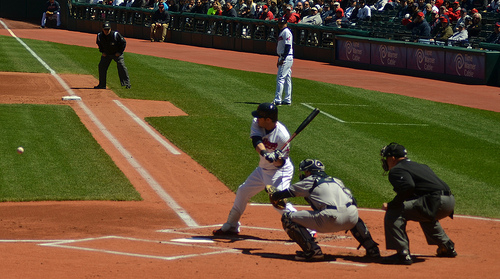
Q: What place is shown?
A: It is a field.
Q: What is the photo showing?
A: It is showing a field.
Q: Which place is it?
A: It is a field.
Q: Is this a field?
A: Yes, it is a field.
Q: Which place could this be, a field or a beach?
A: It is a field.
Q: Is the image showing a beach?
A: No, the picture is showing a field.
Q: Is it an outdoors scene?
A: Yes, it is outdoors.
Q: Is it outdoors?
A: Yes, it is outdoors.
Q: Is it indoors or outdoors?
A: It is outdoors.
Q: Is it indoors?
A: No, it is outdoors.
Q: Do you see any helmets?
A: Yes, there is a helmet.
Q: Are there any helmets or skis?
A: Yes, there is a helmet.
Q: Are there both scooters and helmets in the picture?
A: No, there is a helmet but no scooters.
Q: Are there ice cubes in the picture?
A: No, there are no ice cubes.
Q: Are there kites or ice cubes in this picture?
A: No, there are no ice cubes or kites.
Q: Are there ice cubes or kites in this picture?
A: No, there are no ice cubes or kites.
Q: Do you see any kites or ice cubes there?
A: No, there are no ice cubes or kites.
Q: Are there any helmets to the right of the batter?
A: Yes, there is a helmet to the right of the batter.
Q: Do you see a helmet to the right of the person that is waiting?
A: Yes, there is a helmet to the right of the batter.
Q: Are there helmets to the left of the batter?
A: No, the helmet is to the right of the batter.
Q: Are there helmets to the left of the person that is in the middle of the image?
A: No, the helmet is to the right of the batter.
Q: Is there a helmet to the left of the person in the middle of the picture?
A: No, the helmet is to the right of the batter.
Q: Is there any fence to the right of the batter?
A: No, there is a helmet to the right of the batter.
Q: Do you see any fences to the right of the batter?
A: No, there is a helmet to the right of the batter.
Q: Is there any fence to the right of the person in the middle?
A: No, there is a helmet to the right of the batter.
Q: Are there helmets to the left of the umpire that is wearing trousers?
A: Yes, there is a helmet to the left of the umpire.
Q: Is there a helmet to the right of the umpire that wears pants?
A: No, the helmet is to the left of the umpire.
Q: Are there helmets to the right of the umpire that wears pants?
A: No, the helmet is to the left of the umpire.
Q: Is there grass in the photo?
A: Yes, there is grass.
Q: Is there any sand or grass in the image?
A: Yes, there is grass.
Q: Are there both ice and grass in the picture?
A: No, there is grass but no ice.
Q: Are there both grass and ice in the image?
A: No, there is grass but no ice.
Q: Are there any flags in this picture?
A: No, there are no flags.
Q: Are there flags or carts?
A: No, there are no flags or carts.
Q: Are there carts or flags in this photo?
A: No, there are no flags or carts.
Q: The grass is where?
A: The grass is on the field.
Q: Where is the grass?
A: The grass is on the field.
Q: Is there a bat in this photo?
A: Yes, there is a bat.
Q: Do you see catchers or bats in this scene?
A: Yes, there is a bat.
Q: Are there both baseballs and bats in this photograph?
A: Yes, there are both a bat and a baseball.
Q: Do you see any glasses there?
A: No, there are no glasses.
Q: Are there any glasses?
A: No, there are no glasses.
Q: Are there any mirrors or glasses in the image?
A: No, there are no glasses or mirrors.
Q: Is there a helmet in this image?
A: Yes, there is a helmet.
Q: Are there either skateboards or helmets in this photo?
A: Yes, there is a helmet.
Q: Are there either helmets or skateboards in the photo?
A: Yes, there is a helmet.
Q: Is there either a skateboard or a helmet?
A: Yes, there is a helmet.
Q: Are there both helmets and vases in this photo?
A: No, there is a helmet but no vases.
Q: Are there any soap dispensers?
A: No, there are no soap dispensers.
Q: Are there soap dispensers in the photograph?
A: No, there are no soap dispensers.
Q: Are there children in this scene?
A: No, there are no children.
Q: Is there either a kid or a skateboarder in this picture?
A: No, there are no children or skateboarders.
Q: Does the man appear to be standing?
A: Yes, the man is standing.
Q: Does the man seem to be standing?
A: Yes, the man is standing.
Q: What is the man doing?
A: The man is standing.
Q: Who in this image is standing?
A: The man is standing.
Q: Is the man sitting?
A: No, the man is standing.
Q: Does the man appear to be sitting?
A: No, the man is standing.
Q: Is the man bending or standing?
A: The man is standing.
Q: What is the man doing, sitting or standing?
A: The man is standing.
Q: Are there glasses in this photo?
A: No, there are no glasses.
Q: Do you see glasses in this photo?
A: No, there are no glasses.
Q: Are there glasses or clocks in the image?
A: No, there are no glasses or clocks.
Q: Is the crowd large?
A: Yes, the crowd is large.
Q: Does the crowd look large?
A: Yes, the crowd is large.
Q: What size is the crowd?
A: The crowd is large.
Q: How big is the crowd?
A: The crowd is large.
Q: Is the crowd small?
A: No, the crowd is large.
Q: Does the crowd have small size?
A: No, the crowd is large.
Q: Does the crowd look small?
A: No, the crowd is large.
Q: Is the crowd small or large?
A: The crowd is large.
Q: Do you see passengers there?
A: No, there are no passengers.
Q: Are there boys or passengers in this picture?
A: No, there are no passengers or boys.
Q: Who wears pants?
A: The umpire wears pants.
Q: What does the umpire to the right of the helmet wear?
A: The umpire wears pants.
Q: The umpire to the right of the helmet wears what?
A: The umpire wears pants.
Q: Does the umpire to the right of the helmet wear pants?
A: Yes, the umpire wears pants.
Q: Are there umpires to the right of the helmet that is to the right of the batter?
A: Yes, there is an umpire to the right of the helmet.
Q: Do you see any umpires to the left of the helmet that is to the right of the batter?
A: No, the umpire is to the right of the helmet.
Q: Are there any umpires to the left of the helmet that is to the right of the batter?
A: No, the umpire is to the right of the helmet.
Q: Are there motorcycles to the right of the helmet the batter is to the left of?
A: No, there is an umpire to the right of the helmet.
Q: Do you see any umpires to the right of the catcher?
A: Yes, there is an umpire to the right of the catcher.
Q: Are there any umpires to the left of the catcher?
A: No, the umpire is to the right of the catcher.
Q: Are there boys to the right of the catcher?
A: No, there is an umpire to the right of the catcher.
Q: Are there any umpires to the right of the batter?
A: Yes, there is an umpire to the right of the batter.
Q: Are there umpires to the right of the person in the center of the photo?
A: Yes, there is an umpire to the right of the batter.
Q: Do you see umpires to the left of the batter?
A: No, the umpire is to the right of the batter.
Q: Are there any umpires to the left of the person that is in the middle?
A: No, the umpire is to the right of the batter.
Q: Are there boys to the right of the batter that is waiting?
A: No, there is an umpire to the right of the batter.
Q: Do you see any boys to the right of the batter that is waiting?
A: No, there is an umpire to the right of the batter.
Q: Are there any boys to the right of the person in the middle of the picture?
A: No, there is an umpire to the right of the batter.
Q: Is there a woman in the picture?
A: No, there are no women.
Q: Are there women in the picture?
A: No, there are no women.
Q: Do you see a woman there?
A: No, there are no women.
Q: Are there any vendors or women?
A: No, there are no women or vendors.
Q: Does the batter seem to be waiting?
A: Yes, the batter is waiting.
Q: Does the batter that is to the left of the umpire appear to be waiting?
A: Yes, the batter is waiting.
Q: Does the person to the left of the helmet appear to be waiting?
A: Yes, the batter is waiting.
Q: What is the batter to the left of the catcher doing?
A: The batter is waiting.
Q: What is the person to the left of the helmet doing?
A: The batter is waiting.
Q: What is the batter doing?
A: The batter is waiting.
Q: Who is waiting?
A: The batter is waiting.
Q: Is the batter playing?
A: No, the batter is waiting.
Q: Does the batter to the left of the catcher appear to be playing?
A: No, the batter is waiting.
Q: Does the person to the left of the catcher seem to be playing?
A: No, the batter is waiting.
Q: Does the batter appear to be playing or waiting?
A: The batter is waiting.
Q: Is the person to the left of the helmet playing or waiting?
A: The batter is waiting.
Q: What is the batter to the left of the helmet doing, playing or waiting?
A: The batter is waiting.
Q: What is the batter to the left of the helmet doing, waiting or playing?
A: The batter is waiting.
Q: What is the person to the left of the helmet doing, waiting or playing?
A: The batter is waiting.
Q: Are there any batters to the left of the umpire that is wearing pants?
A: Yes, there is a batter to the left of the umpire.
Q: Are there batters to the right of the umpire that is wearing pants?
A: No, the batter is to the left of the umpire.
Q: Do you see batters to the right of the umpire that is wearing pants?
A: No, the batter is to the left of the umpire.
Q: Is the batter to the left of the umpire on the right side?
A: Yes, the batter is to the left of the umpire.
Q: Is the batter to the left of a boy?
A: No, the batter is to the left of the umpire.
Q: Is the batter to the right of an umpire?
A: No, the batter is to the left of an umpire.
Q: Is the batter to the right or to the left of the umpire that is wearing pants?
A: The batter is to the left of the umpire.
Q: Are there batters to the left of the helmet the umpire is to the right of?
A: Yes, there is a batter to the left of the helmet.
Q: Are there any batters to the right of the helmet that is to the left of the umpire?
A: No, the batter is to the left of the helmet.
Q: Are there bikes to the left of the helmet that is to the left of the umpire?
A: No, there is a batter to the left of the helmet.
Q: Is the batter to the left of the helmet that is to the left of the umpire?
A: Yes, the batter is to the left of the helmet.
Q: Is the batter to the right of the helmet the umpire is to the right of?
A: No, the batter is to the left of the helmet.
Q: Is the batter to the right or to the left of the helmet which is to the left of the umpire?
A: The batter is to the left of the helmet.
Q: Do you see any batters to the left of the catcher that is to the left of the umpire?
A: Yes, there is a batter to the left of the catcher.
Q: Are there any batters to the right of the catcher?
A: No, the batter is to the left of the catcher.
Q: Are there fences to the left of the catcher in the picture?
A: No, there is a batter to the left of the catcher.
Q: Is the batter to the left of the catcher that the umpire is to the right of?
A: Yes, the batter is to the left of the catcher.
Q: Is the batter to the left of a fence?
A: No, the batter is to the left of the catcher.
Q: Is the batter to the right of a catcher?
A: No, the batter is to the left of a catcher.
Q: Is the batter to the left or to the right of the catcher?
A: The batter is to the left of the catcher.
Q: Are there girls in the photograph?
A: No, there are no girls.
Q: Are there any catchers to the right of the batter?
A: Yes, there is a catcher to the right of the batter.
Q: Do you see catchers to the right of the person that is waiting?
A: Yes, there is a catcher to the right of the batter.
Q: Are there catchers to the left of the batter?
A: No, the catcher is to the right of the batter.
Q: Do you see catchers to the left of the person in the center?
A: No, the catcher is to the right of the batter.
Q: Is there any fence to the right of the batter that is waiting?
A: No, there is a catcher to the right of the batter.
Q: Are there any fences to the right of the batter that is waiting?
A: No, there is a catcher to the right of the batter.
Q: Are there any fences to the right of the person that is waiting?
A: No, there is a catcher to the right of the batter.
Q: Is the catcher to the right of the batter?
A: Yes, the catcher is to the right of the batter.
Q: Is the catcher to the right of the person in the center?
A: Yes, the catcher is to the right of the batter.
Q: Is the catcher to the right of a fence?
A: No, the catcher is to the right of the batter.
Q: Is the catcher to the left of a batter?
A: No, the catcher is to the right of a batter.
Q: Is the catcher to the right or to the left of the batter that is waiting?
A: The catcher is to the right of the batter.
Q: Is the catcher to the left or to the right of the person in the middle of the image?
A: The catcher is to the right of the batter.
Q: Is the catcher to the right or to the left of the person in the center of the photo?
A: The catcher is to the right of the batter.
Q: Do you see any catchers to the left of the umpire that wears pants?
A: Yes, there is a catcher to the left of the umpire.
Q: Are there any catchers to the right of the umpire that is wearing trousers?
A: No, the catcher is to the left of the umpire.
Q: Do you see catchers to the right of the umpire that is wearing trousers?
A: No, the catcher is to the left of the umpire.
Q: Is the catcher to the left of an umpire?
A: Yes, the catcher is to the left of an umpire.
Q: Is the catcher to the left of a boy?
A: No, the catcher is to the left of an umpire.